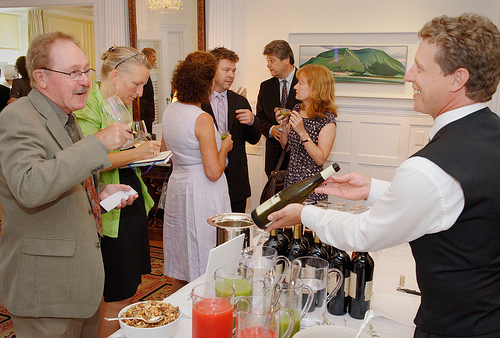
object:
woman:
[160, 50, 235, 285]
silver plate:
[206, 212, 255, 246]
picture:
[298, 42, 408, 96]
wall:
[239, 0, 431, 146]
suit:
[201, 82, 258, 220]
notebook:
[124, 149, 174, 166]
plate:
[114, 141, 498, 333]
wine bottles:
[305, 231, 373, 319]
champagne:
[249, 161, 340, 232]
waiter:
[264, 11, 498, 338]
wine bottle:
[247, 160, 343, 229]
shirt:
[390, 171, 454, 227]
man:
[264, 13, 499, 337]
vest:
[405, 106, 498, 332]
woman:
[79, 45, 166, 337]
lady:
[162, 48, 230, 280]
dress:
[160, 101, 233, 277]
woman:
[274, 64, 340, 204]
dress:
[284, 108, 337, 201]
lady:
[82, 43, 163, 330]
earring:
[108, 84, 120, 97]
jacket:
[76, 82, 161, 246]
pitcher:
[187, 246, 343, 338]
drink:
[189, 283, 235, 336]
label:
[253, 192, 282, 214]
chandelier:
[145, 0, 185, 12]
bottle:
[351, 247, 375, 318]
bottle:
[330, 245, 350, 311]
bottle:
[288, 224, 305, 256]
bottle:
[309, 235, 327, 257]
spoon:
[103, 315, 166, 324]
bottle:
[285, 163, 342, 207]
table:
[108, 205, 425, 337]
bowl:
[116, 298, 178, 337]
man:
[0, 32, 122, 335]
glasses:
[44, 63, 96, 81]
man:
[254, 39, 293, 187]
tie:
[278, 77, 290, 108]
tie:
[62, 108, 107, 226]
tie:
[215, 92, 228, 133]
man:
[208, 46, 256, 218]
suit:
[0, 88, 115, 337]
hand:
[264, 203, 308, 236]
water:
[304, 299, 329, 326]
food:
[137, 305, 160, 318]